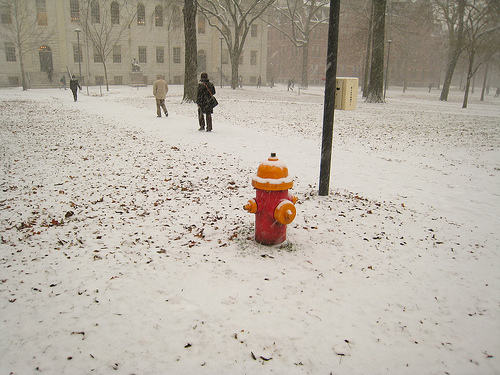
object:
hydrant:
[244, 153, 297, 248]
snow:
[1, 83, 499, 374]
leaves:
[8, 211, 76, 228]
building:
[0, 3, 271, 87]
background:
[1, 2, 499, 91]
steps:
[25, 70, 71, 88]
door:
[39, 45, 55, 83]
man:
[198, 71, 217, 132]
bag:
[199, 79, 218, 112]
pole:
[381, 38, 391, 102]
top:
[251, 151, 295, 192]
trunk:
[103, 62, 110, 90]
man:
[153, 73, 170, 117]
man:
[69, 74, 83, 103]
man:
[257, 74, 262, 90]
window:
[70, 0, 82, 26]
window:
[35, 2, 50, 27]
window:
[73, 42, 84, 61]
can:
[333, 76, 359, 110]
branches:
[202, 0, 275, 25]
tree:
[198, 2, 276, 89]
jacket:
[152, 81, 169, 100]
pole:
[319, 0, 340, 195]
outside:
[0, 1, 499, 373]